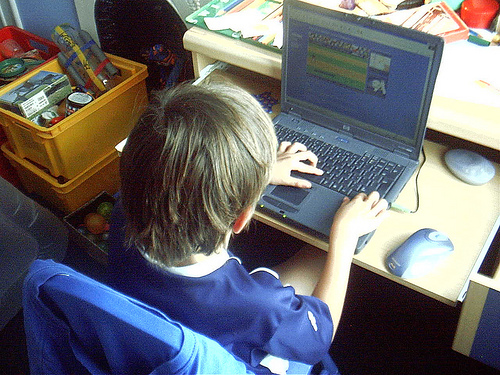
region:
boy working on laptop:
[84, 0, 444, 374]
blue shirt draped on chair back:
[15, 254, 236, 374]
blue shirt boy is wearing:
[107, 196, 334, 370]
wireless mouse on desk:
[378, 223, 451, 284]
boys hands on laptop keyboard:
[267, 135, 392, 240]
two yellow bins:
[1, 36, 141, 214]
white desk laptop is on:
[111, 1, 498, 354]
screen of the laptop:
[283, 7, 430, 142]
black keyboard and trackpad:
[245, 120, 393, 219]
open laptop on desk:
[218, 0, 430, 246]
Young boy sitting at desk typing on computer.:
[101, 62, 387, 365]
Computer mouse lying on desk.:
[385, 225, 458, 278]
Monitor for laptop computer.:
[278, 2, 447, 147]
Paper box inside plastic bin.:
[1, 67, 75, 121]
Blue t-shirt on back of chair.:
[13, 255, 254, 374]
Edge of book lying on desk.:
[448, 270, 499, 361]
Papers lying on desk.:
[203, 8, 282, 53]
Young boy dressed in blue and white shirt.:
[107, 191, 335, 371]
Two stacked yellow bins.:
[3, 40, 150, 206]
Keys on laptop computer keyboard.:
[328, 142, 372, 188]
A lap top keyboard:
[328, 163, 363, 183]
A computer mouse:
[407, 241, 431, 256]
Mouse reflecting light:
[410, 249, 432, 262]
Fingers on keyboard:
[296, 146, 322, 186]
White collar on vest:
[187, 267, 202, 272]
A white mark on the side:
[310, 312, 315, 322]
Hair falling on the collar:
[145, 250, 175, 263]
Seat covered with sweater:
[55, 295, 127, 337]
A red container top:
[465, 6, 487, 23]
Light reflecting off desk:
[448, 203, 487, 232]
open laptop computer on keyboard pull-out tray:
[261, 0, 444, 290]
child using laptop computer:
[117, 12, 428, 363]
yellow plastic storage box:
[16, 45, 144, 164]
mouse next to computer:
[220, 129, 450, 314]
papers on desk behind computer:
[196, 0, 405, 84]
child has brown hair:
[93, 65, 301, 372]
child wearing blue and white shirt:
[114, 92, 387, 355]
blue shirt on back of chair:
[27, 258, 244, 373]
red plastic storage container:
[2, 12, 69, 92]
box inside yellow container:
[4, 61, 75, 169]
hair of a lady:
[179, 159, 227, 224]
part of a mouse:
[397, 254, 431, 307]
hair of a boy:
[181, 183, 234, 257]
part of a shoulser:
[252, 308, 269, 344]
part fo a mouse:
[410, 220, 428, 250]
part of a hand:
[356, 182, 376, 212]